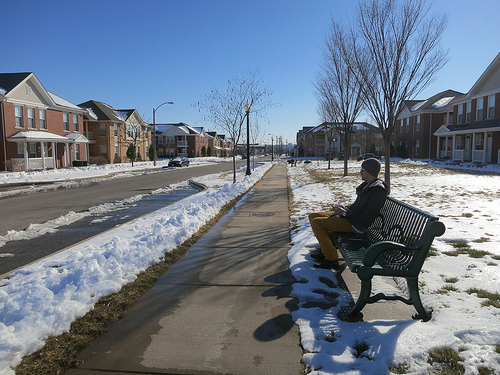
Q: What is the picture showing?
A: It is showing a sidewalk.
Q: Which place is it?
A: It is a sidewalk.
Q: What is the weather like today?
A: It is clear.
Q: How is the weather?
A: It is clear.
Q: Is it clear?
A: Yes, it is clear.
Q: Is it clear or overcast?
A: It is clear.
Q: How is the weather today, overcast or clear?
A: It is clear.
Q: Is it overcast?
A: No, it is clear.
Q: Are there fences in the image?
A: No, there are no fences.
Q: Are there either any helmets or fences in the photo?
A: No, there are no fences or helmets.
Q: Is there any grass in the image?
A: Yes, there is grass.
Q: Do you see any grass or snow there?
A: Yes, there is grass.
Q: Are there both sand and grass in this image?
A: No, there is grass but no sand.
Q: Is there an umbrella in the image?
A: No, there are no umbrellas.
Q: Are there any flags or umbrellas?
A: No, there are no umbrellas or flags.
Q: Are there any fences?
A: No, there are no fences.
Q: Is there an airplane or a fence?
A: No, there are no fences or airplanes.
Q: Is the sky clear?
A: Yes, the sky is clear.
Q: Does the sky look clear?
A: Yes, the sky is clear.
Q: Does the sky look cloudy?
A: No, the sky is clear.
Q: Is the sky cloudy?
A: No, the sky is clear.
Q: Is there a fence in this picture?
A: No, there are no fences.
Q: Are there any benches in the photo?
A: Yes, there is a bench.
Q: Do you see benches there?
A: Yes, there is a bench.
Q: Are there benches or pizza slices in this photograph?
A: Yes, there is a bench.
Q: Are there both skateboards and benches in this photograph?
A: No, there is a bench but no skateboards.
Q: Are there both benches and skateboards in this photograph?
A: No, there is a bench but no skateboards.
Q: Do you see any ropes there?
A: No, there are no ropes.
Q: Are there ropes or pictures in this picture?
A: No, there are no ropes or pictures.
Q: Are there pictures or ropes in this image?
A: No, there are no ropes or pictures.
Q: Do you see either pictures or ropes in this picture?
A: No, there are no ropes or pictures.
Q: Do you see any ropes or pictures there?
A: No, there are no ropes or pictures.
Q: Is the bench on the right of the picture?
A: Yes, the bench is on the right of the image.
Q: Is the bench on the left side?
A: No, the bench is on the right of the image.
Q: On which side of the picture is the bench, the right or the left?
A: The bench is on the right of the image.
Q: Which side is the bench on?
A: The bench is on the right of the image.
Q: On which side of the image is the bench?
A: The bench is on the right of the image.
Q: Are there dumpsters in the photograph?
A: No, there are no dumpsters.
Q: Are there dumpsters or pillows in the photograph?
A: No, there are no dumpsters or pillows.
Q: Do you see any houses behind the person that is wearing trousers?
A: Yes, there is a house behind the man.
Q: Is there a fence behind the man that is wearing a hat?
A: No, there is a house behind the man.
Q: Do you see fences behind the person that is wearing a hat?
A: No, there is a house behind the man.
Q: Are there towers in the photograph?
A: No, there are no towers.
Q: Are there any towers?
A: No, there are no towers.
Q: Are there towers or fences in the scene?
A: No, there are no towers or fences.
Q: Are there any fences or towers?
A: No, there are no towers or fences.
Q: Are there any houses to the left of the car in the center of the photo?
A: Yes, there is a house to the left of the car.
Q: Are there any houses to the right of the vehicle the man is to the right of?
A: No, the house is to the left of the car.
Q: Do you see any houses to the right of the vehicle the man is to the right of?
A: No, the house is to the left of the car.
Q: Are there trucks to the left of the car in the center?
A: No, there is a house to the left of the car.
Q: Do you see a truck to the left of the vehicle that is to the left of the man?
A: No, there is a house to the left of the car.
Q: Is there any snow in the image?
A: Yes, there is snow.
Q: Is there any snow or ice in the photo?
A: Yes, there is snow.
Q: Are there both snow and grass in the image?
A: Yes, there are both snow and grass.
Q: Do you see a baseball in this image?
A: No, there are no baseballs.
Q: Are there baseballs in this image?
A: No, there are no baseballs.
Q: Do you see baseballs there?
A: No, there are no baseballs.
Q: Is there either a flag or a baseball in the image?
A: No, there are no baseballs or flags.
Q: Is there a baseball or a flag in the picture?
A: No, there are no baseballs or flags.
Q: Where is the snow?
A: The snow is on the ground.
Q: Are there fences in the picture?
A: No, there are no fences.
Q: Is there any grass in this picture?
A: Yes, there is grass.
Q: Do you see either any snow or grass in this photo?
A: Yes, there is grass.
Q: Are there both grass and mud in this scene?
A: No, there is grass but no mud.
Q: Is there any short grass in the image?
A: Yes, there is short grass.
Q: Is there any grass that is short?
A: Yes, there is grass that is short.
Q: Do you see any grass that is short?
A: Yes, there is grass that is short.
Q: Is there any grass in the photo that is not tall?
A: Yes, there is short grass.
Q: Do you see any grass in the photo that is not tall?
A: Yes, there is short grass.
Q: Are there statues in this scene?
A: No, there are no statues.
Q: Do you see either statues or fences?
A: No, there are no statues or fences.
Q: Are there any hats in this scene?
A: Yes, there is a hat.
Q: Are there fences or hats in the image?
A: Yes, there is a hat.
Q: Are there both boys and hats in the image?
A: No, there is a hat but no boys.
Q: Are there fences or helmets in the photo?
A: No, there are no fences or helmets.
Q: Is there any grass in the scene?
A: Yes, there is grass.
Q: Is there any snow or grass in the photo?
A: Yes, there is grass.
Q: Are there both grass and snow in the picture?
A: Yes, there are both grass and snow.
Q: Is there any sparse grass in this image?
A: Yes, there is sparse grass.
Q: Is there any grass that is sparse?
A: Yes, there is grass that is sparse.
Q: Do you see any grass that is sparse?
A: Yes, there is grass that is sparse.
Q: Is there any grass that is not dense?
A: Yes, there is sparse grass.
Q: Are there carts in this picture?
A: No, there are no carts.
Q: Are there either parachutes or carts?
A: No, there are no carts or parachutes.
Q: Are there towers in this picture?
A: No, there are no towers.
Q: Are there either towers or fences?
A: No, there are no towers or fences.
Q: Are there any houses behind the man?
A: Yes, there is a house behind the man.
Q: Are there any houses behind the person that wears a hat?
A: Yes, there is a house behind the man.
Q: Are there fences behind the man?
A: No, there is a house behind the man.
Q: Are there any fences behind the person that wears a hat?
A: No, there is a house behind the man.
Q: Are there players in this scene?
A: No, there are no players.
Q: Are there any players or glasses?
A: No, there are no players or glasses.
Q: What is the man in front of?
A: The man is in front of the house.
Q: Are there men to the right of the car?
A: Yes, there is a man to the right of the car.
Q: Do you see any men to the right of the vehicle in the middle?
A: Yes, there is a man to the right of the car.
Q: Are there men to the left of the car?
A: No, the man is to the right of the car.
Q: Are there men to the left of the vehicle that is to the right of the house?
A: No, the man is to the right of the car.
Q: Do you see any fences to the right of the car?
A: No, there is a man to the right of the car.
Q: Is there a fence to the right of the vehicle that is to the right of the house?
A: No, there is a man to the right of the car.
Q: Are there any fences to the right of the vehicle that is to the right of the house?
A: No, there is a man to the right of the car.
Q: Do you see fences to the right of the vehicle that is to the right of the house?
A: No, there is a man to the right of the car.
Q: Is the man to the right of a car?
A: Yes, the man is to the right of a car.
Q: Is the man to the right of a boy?
A: No, the man is to the right of a car.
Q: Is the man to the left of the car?
A: No, the man is to the right of the car.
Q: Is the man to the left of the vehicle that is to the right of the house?
A: No, the man is to the right of the car.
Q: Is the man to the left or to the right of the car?
A: The man is to the right of the car.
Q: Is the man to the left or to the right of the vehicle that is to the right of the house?
A: The man is to the right of the car.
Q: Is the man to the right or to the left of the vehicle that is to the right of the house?
A: The man is to the right of the car.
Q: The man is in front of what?
A: The man is in front of the house.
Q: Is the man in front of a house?
A: Yes, the man is in front of a house.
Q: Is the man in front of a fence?
A: No, the man is in front of a house.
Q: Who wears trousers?
A: The man wears trousers.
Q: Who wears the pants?
A: The man wears trousers.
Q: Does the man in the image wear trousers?
A: Yes, the man wears trousers.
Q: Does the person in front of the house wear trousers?
A: Yes, the man wears trousers.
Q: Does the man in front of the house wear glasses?
A: No, the man wears trousers.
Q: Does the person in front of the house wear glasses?
A: No, the man wears trousers.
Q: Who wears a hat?
A: The man wears a hat.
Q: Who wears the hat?
A: The man wears a hat.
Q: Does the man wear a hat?
A: Yes, the man wears a hat.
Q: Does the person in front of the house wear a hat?
A: Yes, the man wears a hat.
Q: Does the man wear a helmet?
A: No, the man wears a hat.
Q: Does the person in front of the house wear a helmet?
A: No, the man wears a hat.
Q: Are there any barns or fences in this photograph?
A: No, there are no fences or barns.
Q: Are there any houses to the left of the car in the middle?
A: Yes, there is a house to the left of the car.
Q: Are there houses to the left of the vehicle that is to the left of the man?
A: Yes, there is a house to the left of the car.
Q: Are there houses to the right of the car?
A: No, the house is to the left of the car.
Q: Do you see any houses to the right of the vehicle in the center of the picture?
A: No, the house is to the left of the car.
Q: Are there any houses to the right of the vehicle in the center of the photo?
A: No, the house is to the left of the car.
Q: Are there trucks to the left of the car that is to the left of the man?
A: No, there is a house to the left of the car.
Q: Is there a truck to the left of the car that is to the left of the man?
A: No, there is a house to the left of the car.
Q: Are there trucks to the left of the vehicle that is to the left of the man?
A: No, there is a house to the left of the car.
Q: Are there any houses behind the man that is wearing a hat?
A: Yes, there is a house behind the man.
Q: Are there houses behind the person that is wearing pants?
A: Yes, there is a house behind the man.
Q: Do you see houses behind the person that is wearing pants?
A: Yes, there is a house behind the man.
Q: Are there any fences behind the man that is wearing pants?
A: No, there is a house behind the man.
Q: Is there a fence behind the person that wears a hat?
A: No, there is a house behind the man.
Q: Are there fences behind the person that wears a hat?
A: No, there is a house behind the man.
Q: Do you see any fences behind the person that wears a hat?
A: No, there is a house behind the man.